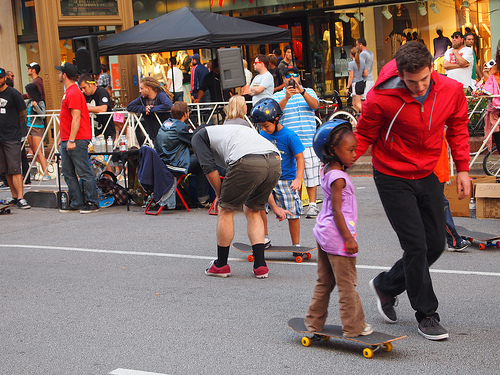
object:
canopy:
[98, 6, 291, 55]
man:
[344, 41, 471, 340]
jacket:
[344, 58, 471, 180]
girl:
[304, 119, 373, 337]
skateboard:
[287, 316, 407, 358]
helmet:
[313, 118, 353, 168]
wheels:
[301, 336, 310, 347]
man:
[191, 124, 293, 278]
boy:
[250, 97, 305, 256]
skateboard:
[232, 242, 317, 262]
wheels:
[296, 256, 303, 263]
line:
[0, 244, 499, 276]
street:
[0, 172, 499, 375]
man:
[271, 65, 321, 215]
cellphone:
[288, 80, 295, 89]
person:
[192, 57, 231, 103]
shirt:
[313, 164, 358, 257]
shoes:
[205, 259, 230, 277]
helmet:
[250, 97, 283, 133]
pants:
[373, 166, 446, 323]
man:
[54, 62, 99, 214]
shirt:
[59, 84, 92, 142]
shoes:
[418, 316, 449, 340]